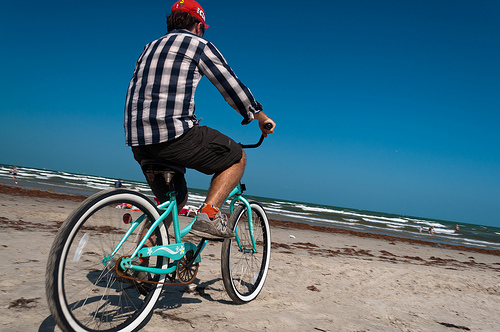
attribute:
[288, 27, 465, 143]
sky — blue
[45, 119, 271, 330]
bike — bright blue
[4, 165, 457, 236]
waves — white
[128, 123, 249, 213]
shorts — black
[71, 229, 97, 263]
reflector — white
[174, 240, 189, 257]
flower — painted white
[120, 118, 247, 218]
shorts — black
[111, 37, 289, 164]
shirt — plaid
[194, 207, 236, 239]
sneaker — grey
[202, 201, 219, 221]
sock — orange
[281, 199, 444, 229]
waves — few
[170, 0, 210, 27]
baseball cap — red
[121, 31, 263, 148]
shirt — black and white, long sleeved, checkered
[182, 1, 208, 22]
hat — red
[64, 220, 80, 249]
rims — white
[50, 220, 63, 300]
tires — black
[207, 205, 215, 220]
socks — orange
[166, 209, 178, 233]
frame — blue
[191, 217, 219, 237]
shoe — athletic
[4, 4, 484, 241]
sky — clear